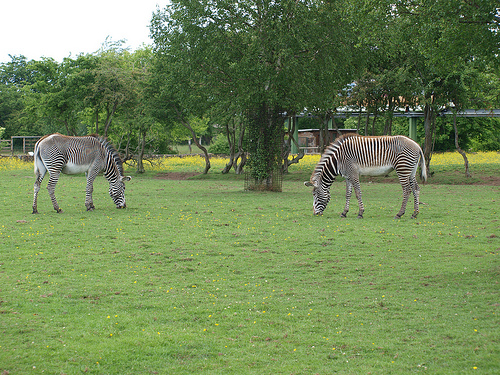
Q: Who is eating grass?
A: The zebras.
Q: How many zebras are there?
A: Two.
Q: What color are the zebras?
A: Black and white.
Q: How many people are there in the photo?
A: None.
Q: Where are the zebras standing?
A: On the grass.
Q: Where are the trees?
A: Behind the zebras.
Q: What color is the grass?
A: Green.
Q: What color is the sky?
A: White.